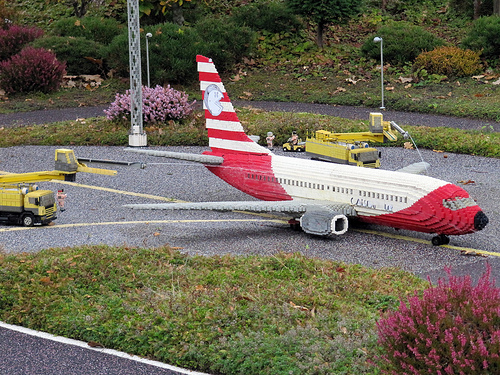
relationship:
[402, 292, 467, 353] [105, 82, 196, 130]
flowers on bush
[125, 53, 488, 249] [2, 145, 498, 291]
airplane on top of pavement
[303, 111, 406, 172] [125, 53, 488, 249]
truck next to airplane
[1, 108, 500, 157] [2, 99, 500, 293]
grass in middle of concrete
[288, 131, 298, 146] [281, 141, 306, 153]
person driving jeep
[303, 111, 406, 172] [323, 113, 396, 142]
truck has lift apparatus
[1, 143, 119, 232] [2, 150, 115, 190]
toys has lift apparatus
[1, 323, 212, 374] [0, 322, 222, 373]
line painted on asphalt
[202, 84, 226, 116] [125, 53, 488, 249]
graphic on tail of plane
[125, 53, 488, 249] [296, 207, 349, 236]
airplane has engine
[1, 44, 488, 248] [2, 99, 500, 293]
toys are on concrete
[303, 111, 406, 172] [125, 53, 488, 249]
truck near airplane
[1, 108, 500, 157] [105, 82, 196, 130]
grass has flowers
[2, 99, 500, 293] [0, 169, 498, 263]
concrete has lines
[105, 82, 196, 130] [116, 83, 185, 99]
pink plant has top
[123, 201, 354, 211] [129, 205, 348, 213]
wing has edge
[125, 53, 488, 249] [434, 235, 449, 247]
airplane has front wheel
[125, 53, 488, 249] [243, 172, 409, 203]
airplane has windows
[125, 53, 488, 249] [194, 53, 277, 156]
airplane has tail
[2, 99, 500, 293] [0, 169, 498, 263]
concrete has yellow line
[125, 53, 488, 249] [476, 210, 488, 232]
airplane has tip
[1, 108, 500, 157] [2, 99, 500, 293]
grass by concrete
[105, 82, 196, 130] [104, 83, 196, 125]
bush has pink flowers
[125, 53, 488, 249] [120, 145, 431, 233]
airplane has wings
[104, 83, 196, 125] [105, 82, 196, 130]
pink flowers are growing on bush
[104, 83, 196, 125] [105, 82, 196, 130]
pink flowers are on bush